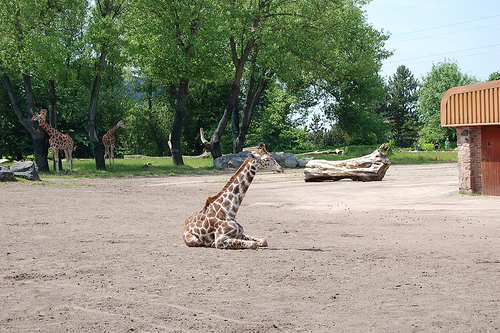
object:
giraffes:
[29, 109, 284, 250]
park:
[0, 0, 499, 332]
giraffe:
[28, 109, 76, 174]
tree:
[0, 0, 89, 178]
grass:
[23, 153, 214, 175]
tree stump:
[302, 144, 392, 181]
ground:
[0, 164, 500, 332]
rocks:
[213, 148, 316, 169]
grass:
[136, 149, 460, 175]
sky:
[370, 0, 499, 77]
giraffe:
[183, 142, 283, 250]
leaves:
[12, 5, 190, 63]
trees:
[0, 0, 420, 165]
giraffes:
[30, 108, 128, 174]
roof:
[441, 79, 500, 126]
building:
[439, 79, 499, 196]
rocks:
[0, 160, 43, 183]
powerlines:
[384, 13, 499, 65]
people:
[433, 137, 452, 148]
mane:
[205, 157, 251, 207]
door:
[479, 126, 499, 195]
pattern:
[206, 205, 232, 239]